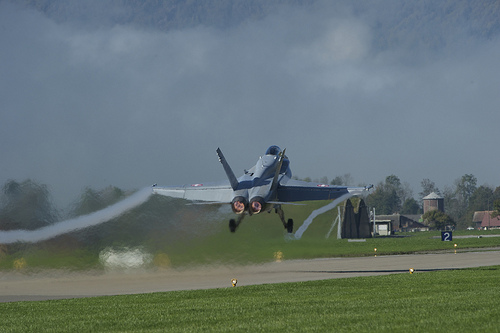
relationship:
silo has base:
[418, 191, 446, 230] [421, 219, 446, 232]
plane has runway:
[134, 139, 374, 230] [0, 217, 499, 308]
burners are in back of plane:
[229, 197, 269, 214] [134, 139, 374, 230]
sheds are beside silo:
[338, 194, 374, 237] [418, 191, 446, 230]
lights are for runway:
[198, 242, 438, 288] [0, 217, 499, 308]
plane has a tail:
[134, 139, 374, 230] [226, 179, 288, 240]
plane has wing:
[134, 139, 374, 230] [151, 173, 235, 208]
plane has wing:
[134, 139, 374, 230] [278, 170, 364, 211]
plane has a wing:
[134, 139, 374, 230] [151, 173, 235, 208]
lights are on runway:
[198, 242, 438, 288] [0, 217, 499, 308]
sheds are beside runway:
[338, 194, 374, 237] [0, 217, 499, 308]